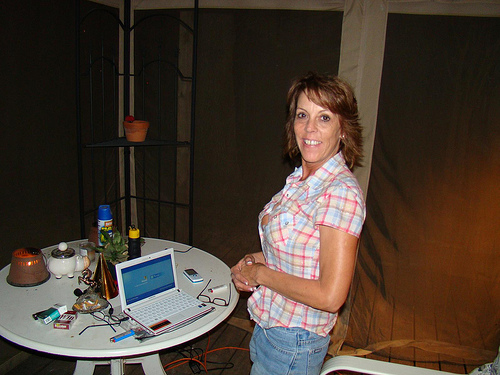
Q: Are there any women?
A: Yes, there is a woman.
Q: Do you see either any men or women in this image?
A: Yes, there is a woman.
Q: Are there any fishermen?
A: No, there are no fishermen.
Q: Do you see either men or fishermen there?
A: No, there are no fishermen or men.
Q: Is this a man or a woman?
A: This is a woman.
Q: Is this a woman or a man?
A: This is a woman.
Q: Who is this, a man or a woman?
A: This is a woman.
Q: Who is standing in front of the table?
A: The woman is standing in front of the table.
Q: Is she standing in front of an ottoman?
A: No, the woman is standing in front of the table.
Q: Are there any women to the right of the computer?
A: Yes, there is a woman to the right of the computer.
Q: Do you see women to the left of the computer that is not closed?
A: No, the woman is to the right of the computer.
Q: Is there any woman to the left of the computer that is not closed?
A: No, the woman is to the right of the computer.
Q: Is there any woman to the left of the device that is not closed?
A: No, the woman is to the right of the computer.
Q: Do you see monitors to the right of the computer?
A: No, there is a woman to the right of the computer.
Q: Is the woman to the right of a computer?
A: Yes, the woman is to the right of a computer.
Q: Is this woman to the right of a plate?
A: No, the woman is to the right of a computer.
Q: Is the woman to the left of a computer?
A: No, the woman is to the right of a computer.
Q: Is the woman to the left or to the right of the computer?
A: The woman is to the right of the computer.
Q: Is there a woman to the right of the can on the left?
A: Yes, there is a woman to the right of the can.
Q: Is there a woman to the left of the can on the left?
A: No, the woman is to the right of the can.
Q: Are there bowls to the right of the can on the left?
A: No, there is a woman to the right of the can.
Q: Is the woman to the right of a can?
A: Yes, the woman is to the right of a can.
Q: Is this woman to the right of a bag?
A: No, the woman is to the right of a can.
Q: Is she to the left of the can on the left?
A: No, the woman is to the right of the can.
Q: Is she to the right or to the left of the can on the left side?
A: The woman is to the right of the can.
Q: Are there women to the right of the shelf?
A: Yes, there is a woman to the right of the shelf.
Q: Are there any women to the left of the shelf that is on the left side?
A: No, the woman is to the right of the shelf.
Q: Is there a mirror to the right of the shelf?
A: No, there is a woman to the right of the shelf.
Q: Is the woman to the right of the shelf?
A: Yes, the woman is to the right of the shelf.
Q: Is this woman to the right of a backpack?
A: No, the woman is to the right of the shelf.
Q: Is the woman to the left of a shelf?
A: No, the woman is to the right of a shelf.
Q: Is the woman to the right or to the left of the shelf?
A: The woman is to the right of the shelf.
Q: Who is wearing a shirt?
A: The woman is wearing a shirt.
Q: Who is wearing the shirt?
A: The woman is wearing a shirt.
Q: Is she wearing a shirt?
A: Yes, the woman is wearing a shirt.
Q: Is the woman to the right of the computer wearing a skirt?
A: No, the woman is wearing a shirt.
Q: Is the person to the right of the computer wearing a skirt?
A: No, the woman is wearing a shirt.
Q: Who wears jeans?
A: The woman wears jeans.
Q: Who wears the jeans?
A: The woman wears jeans.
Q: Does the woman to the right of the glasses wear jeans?
A: Yes, the woman wears jeans.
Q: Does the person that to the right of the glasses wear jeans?
A: Yes, the woman wears jeans.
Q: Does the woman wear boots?
A: No, the woman wears jeans.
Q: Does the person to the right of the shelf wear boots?
A: No, the woman wears jeans.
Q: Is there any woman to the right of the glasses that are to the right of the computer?
A: Yes, there is a woman to the right of the glasses.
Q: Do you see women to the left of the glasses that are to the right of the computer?
A: No, the woman is to the right of the glasses.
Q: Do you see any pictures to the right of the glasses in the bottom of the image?
A: No, there is a woman to the right of the glasses.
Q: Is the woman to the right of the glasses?
A: Yes, the woman is to the right of the glasses.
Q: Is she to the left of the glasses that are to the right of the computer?
A: No, the woman is to the right of the glasses.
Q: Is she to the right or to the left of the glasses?
A: The woman is to the right of the glasses.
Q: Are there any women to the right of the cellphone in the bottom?
A: Yes, there is a woman to the right of the cell phone.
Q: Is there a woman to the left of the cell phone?
A: No, the woman is to the right of the cell phone.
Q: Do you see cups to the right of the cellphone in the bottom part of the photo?
A: No, there is a woman to the right of the cellphone.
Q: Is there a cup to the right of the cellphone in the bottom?
A: No, there is a woman to the right of the cellphone.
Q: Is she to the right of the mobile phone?
A: Yes, the woman is to the right of the mobile phone.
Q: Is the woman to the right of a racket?
A: No, the woman is to the right of the mobile phone.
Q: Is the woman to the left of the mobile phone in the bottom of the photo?
A: No, the woman is to the right of the mobile phone.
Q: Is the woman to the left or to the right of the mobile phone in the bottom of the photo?
A: The woman is to the right of the mobile phone.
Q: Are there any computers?
A: Yes, there is a computer.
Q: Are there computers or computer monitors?
A: Yes, there is a computer.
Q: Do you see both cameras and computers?
A: No, there is a computer but no cameras.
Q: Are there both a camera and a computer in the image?
A: No, there is a computer but no cameras.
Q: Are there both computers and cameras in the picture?
A: No, there is a computer but no cameras.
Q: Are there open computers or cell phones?
A: Yes, there is an open computer.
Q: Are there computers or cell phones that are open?
A: Yes, the computer is open.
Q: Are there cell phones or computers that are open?
A: Yes, the computer is open.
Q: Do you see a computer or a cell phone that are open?
A: Yes, the computer is open.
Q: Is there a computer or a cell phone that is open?
A: Yes, the computer is open.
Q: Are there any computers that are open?
A: Yes, there is an open computer.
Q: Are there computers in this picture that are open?
A: Yes, there is a computer that is open.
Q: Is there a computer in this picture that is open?
A: Yes, there is a computer that is open.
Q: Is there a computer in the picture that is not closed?
A: Yes, there is a open computer.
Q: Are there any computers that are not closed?
A: Yes, there is a open computer.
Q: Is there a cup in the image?
A: No, there are no cups.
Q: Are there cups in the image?
A: No, there are no cups.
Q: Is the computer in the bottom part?
A: Yes, the computer is in the bottom of the image.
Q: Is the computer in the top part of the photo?
A: No, the computer is in the bottom of the image.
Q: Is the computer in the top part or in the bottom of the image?
A: The computer is in the bottom of the image.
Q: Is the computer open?
A: Yes, the computer is open.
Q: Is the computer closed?
A: No, the computer is open.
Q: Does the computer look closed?
A: No, the computer is open.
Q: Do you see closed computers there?
A: No, there is a computer but it is open.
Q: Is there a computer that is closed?
A: No, there is a computer but it is open.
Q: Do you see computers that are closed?
A: No, there is a computer but it is open.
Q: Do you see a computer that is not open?
A: No, there is a computer but it is open.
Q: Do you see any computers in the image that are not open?
A: No, there is a computer but it is open.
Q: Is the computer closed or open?
A: The computer is open.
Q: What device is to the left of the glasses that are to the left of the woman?
A: The device is a computer.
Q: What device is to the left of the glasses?
A: The device is a computer.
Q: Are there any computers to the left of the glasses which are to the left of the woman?
A: Yes, there is a computer to the left of the glasses.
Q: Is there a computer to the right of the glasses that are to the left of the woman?
A: No, the computer is to the left of the glasses.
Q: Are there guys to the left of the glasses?
A: No, there is a computer to the left of the glasses.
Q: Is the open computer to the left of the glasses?
A: Yes, the computer is to the left of the glasses.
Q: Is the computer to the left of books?
A: No, the computer is to the left of the glasses.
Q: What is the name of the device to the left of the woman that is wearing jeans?
A: The device is a computer.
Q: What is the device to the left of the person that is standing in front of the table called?
A: The device is a computer.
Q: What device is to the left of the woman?
A: The device is a computer.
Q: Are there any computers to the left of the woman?
A: Yes, there is a computer to the left of the woman.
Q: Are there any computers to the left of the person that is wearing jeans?
A: Yes, there is a computer to the left of the woman.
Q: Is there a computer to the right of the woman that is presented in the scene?
A: No, the computer is to the left of the woman.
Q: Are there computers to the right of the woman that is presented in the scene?
A: No, the computer is to the left of the woman.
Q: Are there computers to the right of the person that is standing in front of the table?
A: No, the computer is to the left of the woman.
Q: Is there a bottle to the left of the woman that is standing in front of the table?
A: No, there is a computer to the left of the woman.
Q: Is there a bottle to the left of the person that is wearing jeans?
A: No, there is a computer to the left of the woman.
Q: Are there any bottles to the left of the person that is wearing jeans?
A: No, there is a computer to the left of the woman.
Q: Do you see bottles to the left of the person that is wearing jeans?
A: No, there is a computer to the left of the woman.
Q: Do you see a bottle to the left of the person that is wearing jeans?
A: No, there is a computer to the left of the woman.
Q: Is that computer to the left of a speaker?
A: No, the computer is to the left of the woman.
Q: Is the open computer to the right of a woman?
A: No, the computer is to the left of a woman.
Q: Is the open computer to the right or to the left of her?
A: The computer is to the left of the woman.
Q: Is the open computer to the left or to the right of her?
A: The computer is to the left of the woman.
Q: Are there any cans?
A: Yes, there is a can.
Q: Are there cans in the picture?
A: Yes, there is a can.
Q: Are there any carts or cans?
A: Yes, there is a can.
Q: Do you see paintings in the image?
A: No, there are no paintings.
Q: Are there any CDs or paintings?
A: No, there are no paintings or cds.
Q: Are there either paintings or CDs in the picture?
A: No, there are no paintings or cds.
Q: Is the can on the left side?
A: Yes, the can is on the left of the image.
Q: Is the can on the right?
A: No, the can is on the left of the image.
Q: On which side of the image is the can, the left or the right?
A: The can is on the left of the image.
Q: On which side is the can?
A: The can is on the left of the image.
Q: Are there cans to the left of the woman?
A: Yes, there is a can to the left of the woman.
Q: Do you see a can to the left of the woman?
A: Yes, there is a can to the left of the woman.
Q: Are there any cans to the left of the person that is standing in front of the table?
A: Yes, there is a can to the left of the woman.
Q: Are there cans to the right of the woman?
A: No, the can is to the left of the woman.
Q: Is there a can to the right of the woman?
A: No, the can is to the left of the woman.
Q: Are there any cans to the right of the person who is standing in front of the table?
A: No, the can is to the left of the woman.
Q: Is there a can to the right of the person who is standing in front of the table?
A: No, the can is to the left of the woman.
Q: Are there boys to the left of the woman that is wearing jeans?
A: No, there is a can to the left of the woman.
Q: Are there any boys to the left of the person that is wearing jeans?
A: No, there is a can to the left of the woman.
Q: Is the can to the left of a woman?
A: Yes, the can is to the left of a woman.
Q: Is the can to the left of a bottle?
A: No, the can is to the left of a woman.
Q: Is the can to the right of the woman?
A: No, the can is to the left of the woman.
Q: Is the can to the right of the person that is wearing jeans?
A: No, the can is to the left of the woman.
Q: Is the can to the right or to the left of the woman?
A: The can is to the left of the woman.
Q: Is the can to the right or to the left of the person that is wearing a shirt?
A: The can is to the left of the woman.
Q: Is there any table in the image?
A: Yes, there is a table.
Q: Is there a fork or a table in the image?
A: Yes, there is a table.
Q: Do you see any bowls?
A: No, there are no bowls.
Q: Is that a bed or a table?
A: That is a table.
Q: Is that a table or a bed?
A: That is a table.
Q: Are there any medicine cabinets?
A: No, there are no medicine cabinets.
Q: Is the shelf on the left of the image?
A: Yes, the shelf is on the left of the image.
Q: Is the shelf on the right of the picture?
A: No, the shelf is on the left of the image.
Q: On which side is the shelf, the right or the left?
A: The shelf is on the left of the image.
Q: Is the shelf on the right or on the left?
A: The shelf is on the left of the image.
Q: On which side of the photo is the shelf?
A: The shelf is on the left of the image.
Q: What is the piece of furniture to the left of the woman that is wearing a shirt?
A: The piece of furniture is a shelf.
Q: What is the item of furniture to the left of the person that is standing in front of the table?
A: The piece of furniture is a shelf.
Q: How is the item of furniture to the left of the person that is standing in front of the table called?
A: The piece of furniture is a shelf.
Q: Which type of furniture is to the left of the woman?
A: The piece of furniture is a shelf.